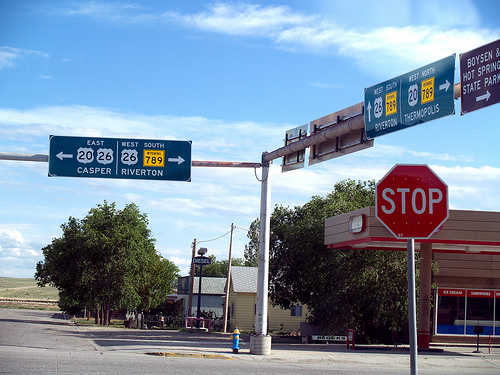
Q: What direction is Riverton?
A: Right.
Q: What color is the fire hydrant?
A: Blue and yellow.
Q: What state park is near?
A: Boysen & Hot Spring State Park.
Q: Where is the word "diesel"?
A: On a sign.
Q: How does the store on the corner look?
A: Vacant.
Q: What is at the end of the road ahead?
A: Empty field.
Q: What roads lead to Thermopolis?
A: 20 West 789 North.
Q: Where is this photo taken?
A: Street.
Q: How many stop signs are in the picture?
A: One.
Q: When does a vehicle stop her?
A: Every time.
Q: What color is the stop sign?
A: Red.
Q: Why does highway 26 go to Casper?
A: Casper is east.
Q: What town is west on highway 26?
A: Riverton.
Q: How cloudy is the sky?
A: Partially cloudy.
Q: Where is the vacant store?
A: Across the street.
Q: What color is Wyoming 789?
A: Yellow.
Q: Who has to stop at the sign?
A: Everyone.